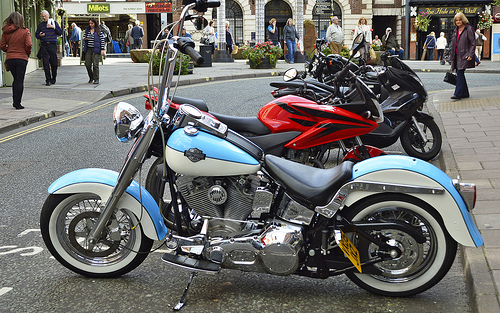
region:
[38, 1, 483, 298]
A line of motorcycles.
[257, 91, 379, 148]
The bike has a red gas tank.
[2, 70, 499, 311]
The ground is asphalt.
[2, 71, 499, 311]
The ground is gray.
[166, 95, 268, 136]
The seat is black.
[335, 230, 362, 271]
The license plate is yellow.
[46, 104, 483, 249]
The bike is blue and white.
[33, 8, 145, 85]
People are in the background.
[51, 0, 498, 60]
Buildings are in the background.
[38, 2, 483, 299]
Three bikes.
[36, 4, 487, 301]
A BLUE AND WHITE MOTORCYCLE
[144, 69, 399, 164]
A RED AND BLACK MOTORCYCLE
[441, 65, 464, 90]
A LADIES HANDBAG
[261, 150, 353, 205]
A BLACK MOTORCYCLE SEAT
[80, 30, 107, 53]
A BLUE AND WHITE STRIPED SHIRT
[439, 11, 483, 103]
A WOMAN HOLDING A PURSE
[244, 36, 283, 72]
A FLOWER PLANTER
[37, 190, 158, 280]
FRONT MOTORCYCLE TIRE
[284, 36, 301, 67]
A PAIR OF BLUE JEANS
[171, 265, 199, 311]
A METAL KICKSTAND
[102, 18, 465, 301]
the motorbikes are parked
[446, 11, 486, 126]
a woman on the sidewalk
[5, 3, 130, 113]
the people are walking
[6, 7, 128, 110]
people are holding their phones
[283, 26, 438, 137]
the bikes are black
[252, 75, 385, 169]
the bike is read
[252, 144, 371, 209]
the seat is gray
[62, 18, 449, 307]
motorbikes are parked at the sidewalk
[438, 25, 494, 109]
woman carrying a bag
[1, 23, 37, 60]
the jacket is brown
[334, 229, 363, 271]
A yellow and black license plate.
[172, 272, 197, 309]
A silver kickstand.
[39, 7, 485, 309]
A light blue and white motorcycle.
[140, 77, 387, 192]
A red and black street motorcycle.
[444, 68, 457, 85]
A black pocketbook.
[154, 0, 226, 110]
Handlebars on a motorcycle.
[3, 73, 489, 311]
The street.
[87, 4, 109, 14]
A green and yellow sign on the building.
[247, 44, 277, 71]
Flowers planted in a large black pot.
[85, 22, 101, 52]
A blue vest.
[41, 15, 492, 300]
a blue and white motorcycle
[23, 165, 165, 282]
the front tire of a motorcycle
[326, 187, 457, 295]
the rear tire of a motorcycle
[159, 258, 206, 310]
the kickstand of a motorcycle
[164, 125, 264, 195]
a blue and white gas tank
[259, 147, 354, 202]
the seat of a motorcycle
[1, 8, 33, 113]
a woman wearing a brown jacket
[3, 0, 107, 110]
people walking on a sidewalk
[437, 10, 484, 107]
a woman with blonde hair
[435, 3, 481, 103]
a woman carrying a purse